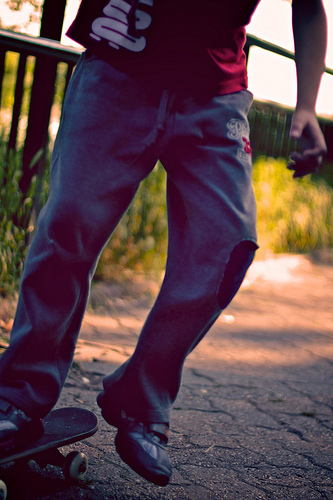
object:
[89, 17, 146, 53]
text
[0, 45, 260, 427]
sweatpants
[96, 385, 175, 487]
black shoe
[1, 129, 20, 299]
tall grass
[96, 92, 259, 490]
leg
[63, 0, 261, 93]
red shirt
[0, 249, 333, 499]
pavement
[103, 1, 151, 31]
letter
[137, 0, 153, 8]
letter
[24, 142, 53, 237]
tall grass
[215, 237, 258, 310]
patch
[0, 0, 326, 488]
person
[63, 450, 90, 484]
wheels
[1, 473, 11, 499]
wheels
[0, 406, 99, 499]
black skateboard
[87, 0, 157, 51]
logo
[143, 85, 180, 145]
drawstring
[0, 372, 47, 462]
tennis shoes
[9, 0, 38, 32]
leaves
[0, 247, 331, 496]
cement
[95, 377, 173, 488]
foot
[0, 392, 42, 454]
foot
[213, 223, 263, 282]
knee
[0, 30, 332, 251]
fence